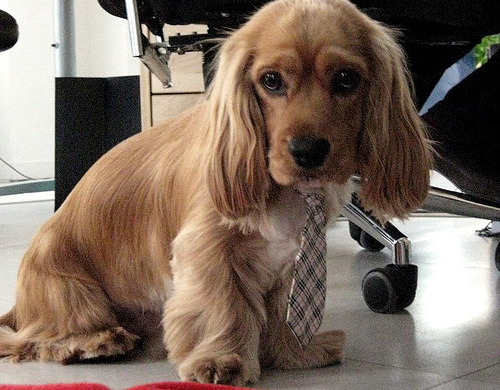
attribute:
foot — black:
[362, 264, 417, 314]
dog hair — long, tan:
[4, 0, 432, 380]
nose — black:
[287, 135, 335, 169]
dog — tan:
[0, 1, 439, 388]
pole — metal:
[47, 4, 87, 76]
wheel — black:
[361, 265, 418, 312]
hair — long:
[211, 53, 265, 216]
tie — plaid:
[281, 182, 329, 351]